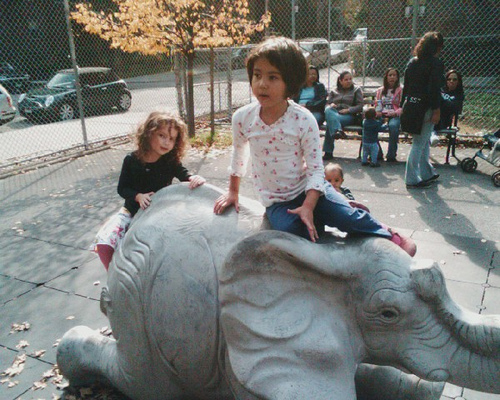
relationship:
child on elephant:
[223, 38, 417, 257] [56, 180, 499, 398]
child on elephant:
[92, 103, 208, 268] [56, 180, 499, 398]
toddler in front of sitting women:
[360, 104, 385, 170] [363, 62, 402, 161]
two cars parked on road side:
[0, 62, 137, 130] [1, 44, 228, 119]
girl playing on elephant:
[95, 110, 205, 272] [56, 180, 499, 398]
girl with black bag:
[399, 27, 445, 186] [395, 91, 429, 138]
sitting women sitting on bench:
[295, 63, 329, 124] [288, 87, 471, 171]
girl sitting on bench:
[321, 70, 363, 159] [288, 87, 471, 171]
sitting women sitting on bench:
[363, 62, 402, 161] [288, 87, 471, 171]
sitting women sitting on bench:
[434, 66, 465, 133] [288, 87, 471, 171]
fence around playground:
[162, 4, 496, 135] [4, 3, 498, 395]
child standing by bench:
[357, 107, 382, 162] [314, 120, 456, 166]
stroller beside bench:
[459, 124, 499, 185] [286, 79, 461, 161]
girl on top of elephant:
[95, 110, 205, 272] [56, 173, 497, 398]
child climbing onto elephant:
[92, 111, 207, 267] [56, 180, 499, 398]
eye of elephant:
[377, 307, 400, 322] [56, 180, 499, 398]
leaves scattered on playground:
[1, 302, 66, 391] [21, 118, 495, 394]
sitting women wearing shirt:
[295, 63, 329, 124] [301, 85, 318, 110]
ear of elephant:
[228, 228, 357, 398] [56, 180, 499, 398]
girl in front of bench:
[399, 27, 445, 186] [314, 99, 459, 166]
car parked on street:
[296, 31, 350, 79] [0, 40, 359, 165]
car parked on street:
[16, 56, 130, 121] [0, 40, 359, 165]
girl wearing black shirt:
[124, 107, 187, 179] [126, 151, 181, 186]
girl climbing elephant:
[124, 107, 187, 179] [56, 180, 499, 398]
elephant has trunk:
[56, 173, 497, 398] [401, 261, 499, 391]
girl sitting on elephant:
[95, 110, 205, 272] [56, 180, 499, 398]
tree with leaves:
[69, 0, 276, 135] [67, 0, 272, 57]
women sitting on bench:
[268, 44, 474, 154] [283, 101, 470, 163]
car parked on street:
[16, 56, 130, 121] [1, 60, 254, 170]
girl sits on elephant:
[95, 110, 205, 272] [56, 173, 497, 398]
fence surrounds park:
[1, 2, 243, 179] [0, 3, 119, 80]